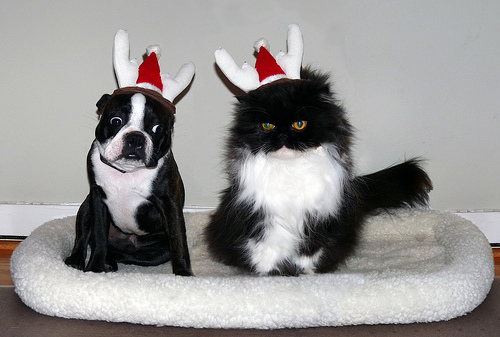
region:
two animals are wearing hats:
[91, 38, 394, 122]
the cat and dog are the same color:
[62, 73, 482, 219]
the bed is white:
[79, 266, 206, 334]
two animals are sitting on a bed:
[103, 226, 380, 335]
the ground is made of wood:
[9, 290, 36, 318]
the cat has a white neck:
[220, 163, 429, 237]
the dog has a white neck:
[100, 167, 202, 214]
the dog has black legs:
[71, 210, 179, 291]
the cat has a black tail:
[353, 171, 435, 234]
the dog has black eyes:
[101, 106, 228, 186]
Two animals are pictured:
[64, 40, 443, 275]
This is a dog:
[64, 48, 201, 287]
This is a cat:
[208, 54, 435, 286]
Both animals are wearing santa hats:
[67, 27, 437, 283]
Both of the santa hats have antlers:
[78, 20, 344, 96]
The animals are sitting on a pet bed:
[12, 50, 498, 327]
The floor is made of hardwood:
[3, 243, 15, 284]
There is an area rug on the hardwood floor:
[4, 291, 66, 335]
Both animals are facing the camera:
[55, 46, 447, 276]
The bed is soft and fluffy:
[13, 208, 491, 323]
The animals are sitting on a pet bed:
[18, 201, 489, 308]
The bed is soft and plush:
[11, 215, 486, 335]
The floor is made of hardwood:
[0, 233, 14, 280]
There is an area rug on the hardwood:
[5, 305, 47, 334]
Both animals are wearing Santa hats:
[98, 28, 336, 98]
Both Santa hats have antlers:
[88, 28, 342, 87]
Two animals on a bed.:
[38, 25, 479, 327]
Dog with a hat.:
[109, 25, 207, 143]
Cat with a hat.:
[203, 34, 365, 132]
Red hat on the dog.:
[86, 38, 231, 136]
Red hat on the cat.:
[196, 30, 362, 127]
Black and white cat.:
[214, 126, 407, 266]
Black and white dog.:
[75, 85, 223, 254]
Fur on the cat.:
[232, 128, 362, 221]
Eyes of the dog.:
[97, 103, 174, 138]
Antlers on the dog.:
[108, 36, 246, 105]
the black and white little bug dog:
[70, 88, 197, 278]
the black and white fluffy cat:
[215, 85, 425, 270]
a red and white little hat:
[112, 27, 189, 98]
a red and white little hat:
[214, 24, 301, 84]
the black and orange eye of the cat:
[261, 118, 273, 130]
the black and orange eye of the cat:
[292, 116, 304, 129]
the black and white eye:
[107, 116, 123, 128]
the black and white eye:
[151, 118, 163, 133]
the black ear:
[93, 90, 113, 110]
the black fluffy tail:
[326, 152, 428, 258]